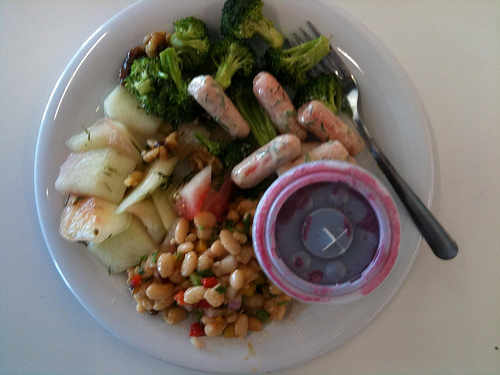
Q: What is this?
A: Food.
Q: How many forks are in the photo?
A: One.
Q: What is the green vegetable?
A: Broccoli.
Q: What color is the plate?
A: White.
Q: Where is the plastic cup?
A: On plate.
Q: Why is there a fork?
A: Pick up food.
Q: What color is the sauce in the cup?
A: Red.